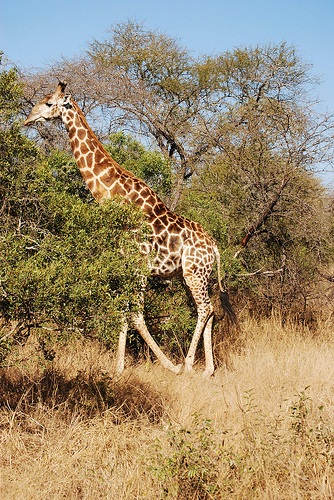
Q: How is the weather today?
A: It is clear.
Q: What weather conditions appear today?
A: It is clear.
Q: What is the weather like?
A: It is clear.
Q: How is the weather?
A: It is clear.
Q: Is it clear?
A: Yes, it is clear.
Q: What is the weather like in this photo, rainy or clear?
A: It is clear.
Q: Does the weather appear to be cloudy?
A: No, it is clear.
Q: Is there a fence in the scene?
A: No, there are no fences.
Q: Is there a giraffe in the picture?
A: Yes, there is a giraffe.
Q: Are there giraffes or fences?
A: Yes, there is a giraffe.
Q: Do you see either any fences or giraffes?
A: Yes, there is a giraffe.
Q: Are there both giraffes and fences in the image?
A: No, there is a giraffe but no fences.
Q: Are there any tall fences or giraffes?
A: Yes, there is a tall giraffe.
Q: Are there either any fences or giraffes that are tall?
A: Yes, the giraffe is tall.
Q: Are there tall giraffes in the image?
A: Yes, there is a tall giraffe.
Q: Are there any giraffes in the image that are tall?
A: Yes, there is a giraffe that is tall.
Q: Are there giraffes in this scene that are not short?
A: Yes, there is a tall giraffe.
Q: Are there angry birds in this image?
A: No, there are no angry birds.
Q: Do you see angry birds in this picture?
A: No, there are no angry birds.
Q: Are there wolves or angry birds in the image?
A: No, there are no angry birds or wolves.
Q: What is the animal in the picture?
A: The animal is a giraffe.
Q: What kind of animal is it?
A: The animal is a giraffe.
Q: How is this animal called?
A: This is a giraffe.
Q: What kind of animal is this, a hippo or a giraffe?
A: This is a giraffe.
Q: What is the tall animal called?
A: The animal is a giraffe.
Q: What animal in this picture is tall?
A: The animal is a giraffe.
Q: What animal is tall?
A: The animal is a giraffe.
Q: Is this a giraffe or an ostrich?
A: This is a giraffe.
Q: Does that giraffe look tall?
A: Yes, the giraffe is tall.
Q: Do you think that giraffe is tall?
A: Yes, the giraffe is tall.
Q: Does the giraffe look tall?
A: Yes, the giraffe is tall.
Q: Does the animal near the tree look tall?
A: Yes, the giraffe is tall.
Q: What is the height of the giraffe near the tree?
A: The giraffe is tall.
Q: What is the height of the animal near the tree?
A: The giraffe is tall.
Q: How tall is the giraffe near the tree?
A: The giraffe is tall.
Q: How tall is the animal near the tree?
A: The giraffe is tall.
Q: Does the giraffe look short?
A: No, the giraffe is tall.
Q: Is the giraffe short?
A: No, the giraffe is tall.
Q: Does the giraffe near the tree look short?
A: No, the giraffe is tall.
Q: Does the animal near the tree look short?
A: No, the giraffe is tall.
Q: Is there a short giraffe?
A: No, there is a giraffe but it is tall.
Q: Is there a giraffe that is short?
A: No, there is a giraffe but it is tall.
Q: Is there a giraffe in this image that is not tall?
A: No, there is a giraffe but it is tall.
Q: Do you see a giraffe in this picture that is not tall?
A: No, there is a giraffe but it is tall.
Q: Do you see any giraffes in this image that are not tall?
A: No, there is a giraffe but it is tall.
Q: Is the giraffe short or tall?
A: The giraffe is tall.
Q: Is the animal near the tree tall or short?
A: The giraffe is tall.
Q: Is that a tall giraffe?
A: Yes, that is a tall giraffe.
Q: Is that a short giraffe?
A: No, that is a tall giraffe.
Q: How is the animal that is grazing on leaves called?
A: The animal is a giraffe.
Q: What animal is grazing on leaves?
A: The animal is a giraffe.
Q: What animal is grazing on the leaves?
A: The animal is a giraffe.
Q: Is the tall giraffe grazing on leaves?
A: Yes, the giraffe is grazing on leaves.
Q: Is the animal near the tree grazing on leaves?
A: Yes, the giraffe is grazing on leaves.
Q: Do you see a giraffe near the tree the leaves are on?
A: Yes, there is a giraffe near the tree.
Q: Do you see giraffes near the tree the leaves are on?
A: Yes, there is a giraffe near the tree.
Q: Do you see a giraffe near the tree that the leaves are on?
A: Yes, there is a giraffe near the tree.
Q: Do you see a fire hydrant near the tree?
A: No, there is a giraffe near the tree.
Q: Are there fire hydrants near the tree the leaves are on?
A: No, there is a giraffe near the tree.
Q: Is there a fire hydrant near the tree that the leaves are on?
A: No, there is a giraffe near the tree.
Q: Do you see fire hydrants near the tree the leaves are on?
A: No, there is a giraffe near the tree.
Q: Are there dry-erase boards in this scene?
A: No, there are no dry-erase boards.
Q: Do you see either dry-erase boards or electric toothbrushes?
A: No, there are no dry-erase boards or electric toothbrushes.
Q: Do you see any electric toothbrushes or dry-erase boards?
A: No, there are no dry-erase boards or electric toothbrushes.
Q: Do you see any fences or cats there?
A: No, there are no fences or cats.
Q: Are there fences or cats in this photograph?
A: No, there are no fences or cats.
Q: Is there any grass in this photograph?
A: Yes, there is grass.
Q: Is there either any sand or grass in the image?
A: Yes, there is grass.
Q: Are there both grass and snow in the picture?
A: No, there is grass but no snow.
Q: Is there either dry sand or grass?
A: Yes, there is dry grass.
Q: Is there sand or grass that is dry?
A: Yes, the grass is dry.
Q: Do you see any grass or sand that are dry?
A: Yes, the grass is dry.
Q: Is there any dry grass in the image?
A: Yes, there is dry grass.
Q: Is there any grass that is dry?
A: Yes, there is grass that is dry.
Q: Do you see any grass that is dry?
A: Yes, there is grass that is dry.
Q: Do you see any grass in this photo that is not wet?
A: Yes, there is dry grass.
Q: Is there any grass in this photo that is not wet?
A: Yes, there is dry grass.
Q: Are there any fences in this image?
A: No, there are no fences.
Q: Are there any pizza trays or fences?
A: No, there are no fences or pizza trays.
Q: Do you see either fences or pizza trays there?
A: No, there are no fences or pizza trays.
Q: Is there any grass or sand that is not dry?
A: No, there is grass but it is dry.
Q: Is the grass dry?
A: Yes, the grass is dry.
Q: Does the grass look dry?
A: Yes, the grass is dry.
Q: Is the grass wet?
A: No, the grass is dry.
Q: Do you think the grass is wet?
A: No, the grass is dry.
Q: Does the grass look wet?
A: No, the grass is dry.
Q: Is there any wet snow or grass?
A: No, there is grass but it is dry.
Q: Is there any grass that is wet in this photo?
A: No, there is grass but it is dry.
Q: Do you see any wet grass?
A: No, there is grass but it is dry.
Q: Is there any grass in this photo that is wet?
A: No, there is grass but it is dry.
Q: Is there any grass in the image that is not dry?
A: No, there is grass but it is dry.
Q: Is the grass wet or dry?
A: The grass is dry.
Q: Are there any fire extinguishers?
A: No, there are no fire extinguishers.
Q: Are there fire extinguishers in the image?
A: No, there are no fire extinguishers.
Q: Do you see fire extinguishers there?
A: No, there are no fire extinguishers.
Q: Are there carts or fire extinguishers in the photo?
A: No, there are no fire extinguishers or carts.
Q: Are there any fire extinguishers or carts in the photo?
A: No, there are no fire extinguishers or carts.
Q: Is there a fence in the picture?
A: No, there are no fences.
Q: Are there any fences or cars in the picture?
A: No, there are no fences or cars.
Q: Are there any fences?
A: No, there are no fences.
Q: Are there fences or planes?
A: No, there are no fences or planes.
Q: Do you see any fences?
A: No, there are no fences.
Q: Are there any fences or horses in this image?
A: No, there are no fences or horses.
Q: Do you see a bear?
A: No, there are no bears.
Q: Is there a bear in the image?
A: No, there are no bears.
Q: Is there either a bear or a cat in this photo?
A: No, there are no bears or cats.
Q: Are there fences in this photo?
A: No, there are no fences.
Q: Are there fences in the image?
A: No, there are no fences.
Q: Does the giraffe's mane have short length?
A: Yes, the mane is short.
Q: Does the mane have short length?
A: Yes, the mane is short.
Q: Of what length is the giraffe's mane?
A: The mane is short.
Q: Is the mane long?
A: No, the mane is short.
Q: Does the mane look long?
A: No, the mane is short.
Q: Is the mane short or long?
A: The mane is short.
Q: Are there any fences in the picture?
A: No, there are no fences.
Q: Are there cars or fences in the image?
A: No, there are no fences or cars.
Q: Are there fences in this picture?
A: No, there are no fences.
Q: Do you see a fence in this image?
A: No, there are no fences.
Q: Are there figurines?
A: No, there are no figurines.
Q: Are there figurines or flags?
A: No, there are no figurines or flags.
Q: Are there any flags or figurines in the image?
A: No, there are no figurines or flags.